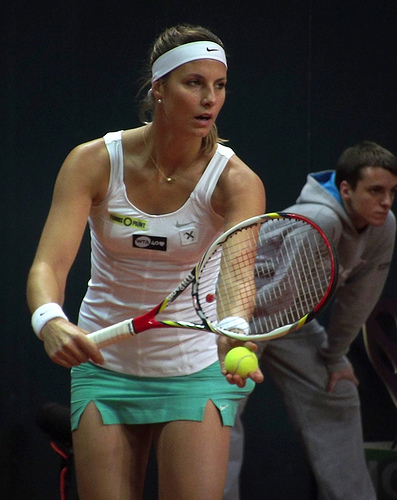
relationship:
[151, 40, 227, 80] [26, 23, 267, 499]
headband on head of player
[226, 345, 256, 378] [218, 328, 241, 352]
ball in players left hand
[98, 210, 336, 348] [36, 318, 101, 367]
racquet in womans right hand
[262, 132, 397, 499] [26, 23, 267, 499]
man behind player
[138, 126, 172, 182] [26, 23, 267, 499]
necklace on ten player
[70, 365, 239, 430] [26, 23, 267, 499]
skirt on player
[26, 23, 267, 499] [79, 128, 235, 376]
player wearing a tanktop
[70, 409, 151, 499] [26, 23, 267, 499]
leg of player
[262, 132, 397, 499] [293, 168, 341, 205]
man inside of jacket hood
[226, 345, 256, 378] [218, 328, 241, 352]
ball in left hand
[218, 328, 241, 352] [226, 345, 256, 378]
left hand holding onto a ball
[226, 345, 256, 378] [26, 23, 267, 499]
ball for player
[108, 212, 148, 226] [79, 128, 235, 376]
tag on tanktop